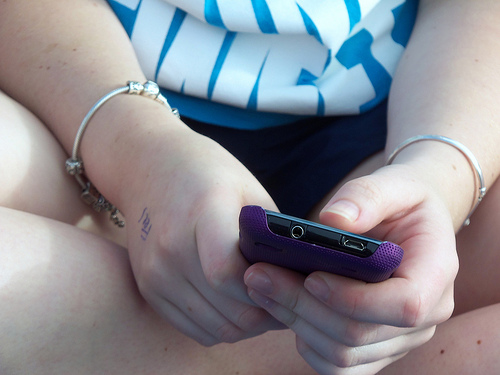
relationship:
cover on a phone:
[239, 215, 262, 265] [241, 206, 397, 281]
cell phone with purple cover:
[238, 204, 405, 283] [241, 210, 405, 289]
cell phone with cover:
[236, 204, 405, 284] [241, 227, 381, 282]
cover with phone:
[252, 238, 282, 260] [239, 205, 409, 272]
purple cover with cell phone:
[237, 205, 404, 283] [218, 190, 441, 300]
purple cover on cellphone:
[235, 203, 419, 302] [232, 205, 412, 285]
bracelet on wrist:
[382, 126, 487, 229] [384, 155, 467, 230]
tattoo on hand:
[82, 164, 174, 296] [356, 22, 481, 298]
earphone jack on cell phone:
[292, 224, 306, 238] [238, 204, 405, 283]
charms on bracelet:
[126, 79, 181, 120] [63, 79, 180, 229]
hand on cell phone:
[123, 128, 292, 348] [236, 204, 405, 284]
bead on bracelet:
[143, 80, 160, 100] [59, 81, 198, 228]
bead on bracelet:
[143, 78, 160, 101] [63, 79, 180, 229]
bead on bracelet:
[143, 80, 160, 100] [47, 75, 188, 225]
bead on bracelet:
[62, 157, 84, 174] [47, 75, 188, 225]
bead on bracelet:
[471, 179, 491, 204] [382, 126, 487, 229]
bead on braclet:
[63, 159, 83, 175] [62, 72, 182, 223]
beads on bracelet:
[113, 73, 174, 106] [46, 55, 193, 225]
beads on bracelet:
[62, 157, 127, 227] [68, 80, 175, 220]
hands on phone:
[100, 132, 475, 371] [234, 200, 401, 281]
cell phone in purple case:
[238, 204, 405, 283] [234, 200, 397, 285]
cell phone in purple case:
[238, 204, 405, 283] [239, 205, 403, 281]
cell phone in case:
[238, 204, 405, 283] [238, 204, 403, 278]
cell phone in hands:
[238, 204, 405, 283] [100, 132, 475, 371]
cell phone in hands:
[238, 204, 405, 283] [116, 133, 463, 363]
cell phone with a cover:
[236, 204, 405, 284] [238, 204, 402, 279]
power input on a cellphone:
[341, 236, 367, 249] [204, 216, 412, 314]